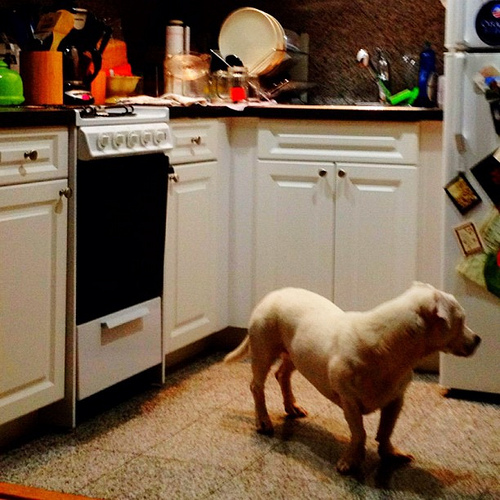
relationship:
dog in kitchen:
[227, 279, 480, 475] [3, 1, 500, 497]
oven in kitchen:
[70, 117, 171, 429] [3, 1, 500, 497]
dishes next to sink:
[215, 7, 286, 78] [284, 92, 431, 113]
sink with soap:
[284, 92, 431, 113] [419, 48, 439, 107]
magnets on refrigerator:
[445, 172, 486, 256] [441, 0, 500, 402]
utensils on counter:
[28, 9, 72, 108] [2, 98, 271, 127]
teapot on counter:
[0, 62, 27, 105] [2, 98, 271, 127]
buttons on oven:
[96, 128, 168, 151] [70, 117, 171, 429]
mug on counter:
[215, 65, 252, 105] [2, 98, 271, 127]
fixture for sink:
[358, 46, 393, 104] [284, 92, 431, 113]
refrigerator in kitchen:
[441, 0, 500, 402] [3, 1, 500, 497]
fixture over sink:
[358, 46, 393, 104] [284, 92, 431, 113]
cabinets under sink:
[167, 122, 434, 365] [284, 92, 431, 113]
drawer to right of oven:
[168, 120, 225, 165] [70, 117, 171, 429]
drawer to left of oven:
[0, 127, 70, 188] [70, 117, 171, 429]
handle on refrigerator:
[447, 0, 470, 155] [441, 0, 500, 402]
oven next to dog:
[70, 117, 171, 429] [227, 279, 480, 475]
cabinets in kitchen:
[167, 122, 434, 365] [3, 1, 500, 497]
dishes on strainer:
[215, 7, 286, 78] [210, 49, 317, 104]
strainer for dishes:
[210, 49, 317, 104] [215, 7, 286, 78]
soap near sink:
[419, 48, 439, 107] [284, 92, 431, 113]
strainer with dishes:
[210, 49, 317, 104] [215, 7, 286, 78]